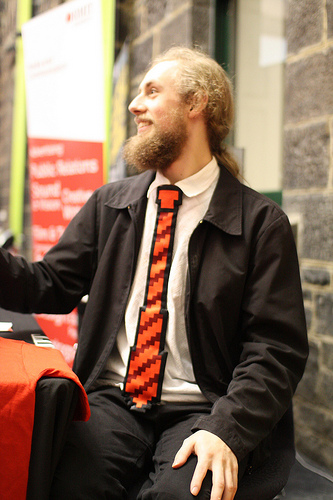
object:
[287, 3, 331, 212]
wall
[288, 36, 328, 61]
line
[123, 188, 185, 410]
tie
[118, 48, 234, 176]
head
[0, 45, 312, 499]
man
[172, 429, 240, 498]
hand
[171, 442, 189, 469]
thumb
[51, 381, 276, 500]
pants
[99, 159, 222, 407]
shirt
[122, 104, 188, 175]
beard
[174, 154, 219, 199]
collar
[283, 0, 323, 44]
brick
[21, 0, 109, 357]
sign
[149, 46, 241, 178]
hair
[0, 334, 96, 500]
shirt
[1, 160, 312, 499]
jacket